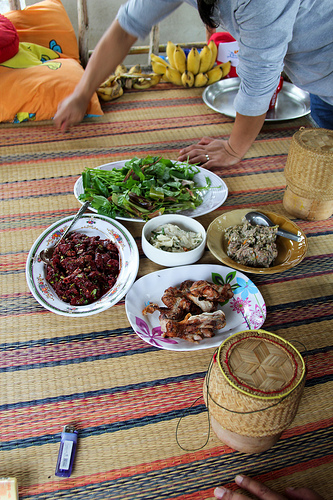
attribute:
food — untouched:
[22, 134, 310, 353]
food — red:
[42, 172, 304, 459]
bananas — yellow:
[156, 46, 234, 86]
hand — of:
[179, 136, 237, 165]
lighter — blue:
[53, 420, 82, 480]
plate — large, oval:
[77, 157, 229, 217]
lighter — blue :
[52, 422, 82, 477]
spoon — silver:
[38, 199, 92, 264]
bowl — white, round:
[137, 212, 207, 267]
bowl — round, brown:
[171, 168, 299, 271]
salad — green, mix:
[79, 157, 210, 215]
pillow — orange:
[0, 0, 105, 118]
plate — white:
[25, 211, 139, 316]